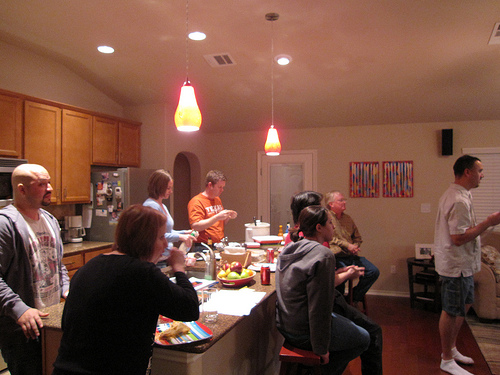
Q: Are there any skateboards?
A: No, there are no skateboards.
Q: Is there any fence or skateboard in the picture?
A: No, there are no skateboards or fences.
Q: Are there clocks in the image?
A: No, there are no clocks.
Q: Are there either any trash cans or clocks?
A: No, there are no clocks or trash cans.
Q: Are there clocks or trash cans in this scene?
A: No, there are no clocks or trash cans.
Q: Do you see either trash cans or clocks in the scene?
A: No, there are no clocks or trash cans.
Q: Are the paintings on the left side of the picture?
A: No, the paintings are on the right of the image.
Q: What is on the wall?
A: The paintings are on the wall.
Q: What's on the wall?
A: The paintings are on the wall.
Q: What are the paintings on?
A: The paintings are on the wall.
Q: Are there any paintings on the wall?
A: Yes, there are paintings on the wall.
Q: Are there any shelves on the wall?
A: No, there are paintings on the wall.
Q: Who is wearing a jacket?
A: The girl is wearing a jacket.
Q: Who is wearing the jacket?
A: The girl is wearing a jacket.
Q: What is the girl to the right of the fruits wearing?
A: The girl is wearing a jacket.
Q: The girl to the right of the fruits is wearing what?
A: The girl is wearing a jacket.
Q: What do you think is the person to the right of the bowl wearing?
A: The girl is wearing a jacket.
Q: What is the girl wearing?
A: The girl is wearing a jacket.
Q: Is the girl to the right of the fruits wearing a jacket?
A: Yes, the girl is wearing a jacket.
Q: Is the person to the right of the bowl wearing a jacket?
A: Yes, the girl is wearing a jacket.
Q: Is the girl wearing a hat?
A: No, the girl is wearing a jacket.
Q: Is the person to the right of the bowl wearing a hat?
A: No, the girl is wearing a jacket.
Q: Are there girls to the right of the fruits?
A: Yes, there is a girl to the right of the fruits.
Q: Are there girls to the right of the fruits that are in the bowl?
A: Yes, there is a girl to the right of the fruits.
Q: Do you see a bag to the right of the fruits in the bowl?
A: No, there is a girl to the right of the fruits.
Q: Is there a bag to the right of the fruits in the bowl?
A: No, there is a girl to the right of the fruits.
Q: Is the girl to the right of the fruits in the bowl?
A: Yes, the girl is to the right of the fruits.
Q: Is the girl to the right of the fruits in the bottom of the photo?
A: Yes, the girl is to the right of the fruits.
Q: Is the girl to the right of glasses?
A: No, the girl is to the right of the fruits.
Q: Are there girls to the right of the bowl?
A: Yes, there is a girl to the right of the bowl.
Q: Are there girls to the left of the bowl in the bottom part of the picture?
A: No, the girl is to the right of the bowl.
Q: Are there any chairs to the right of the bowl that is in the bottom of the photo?
A: No, there is a girl to the right of the bowl.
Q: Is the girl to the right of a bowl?
A: Yes, the girl is to the right of a bowl.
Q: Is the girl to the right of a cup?
A: No, the girl is to the right of a bowl.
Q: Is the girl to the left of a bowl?
A: No, the girl is to the right of a bowl.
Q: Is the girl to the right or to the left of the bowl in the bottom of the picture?
A: The girl is to the right of the bowl.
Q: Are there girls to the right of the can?
A: Yes, there is a girl to the right of the can.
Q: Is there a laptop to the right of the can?
A: No, there is a girl to the right of the can.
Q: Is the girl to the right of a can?
A: Yes, the girl is to the right of a can.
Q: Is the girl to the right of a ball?
A: No, the girl is to the right of a can.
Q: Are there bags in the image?
A: No, there are no bags.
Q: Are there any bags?
A: No, there are no bags.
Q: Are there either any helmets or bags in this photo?
A: No, there are no bags or helmets.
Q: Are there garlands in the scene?
A: No, there are no garlands.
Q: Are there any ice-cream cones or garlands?
A: No, there are no garlands or ice-cream cones.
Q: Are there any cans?
A: Yes, there is a can.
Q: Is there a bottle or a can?
A: Yes, there is a can.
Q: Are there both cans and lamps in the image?
A: Yes, there are both a can and a lamp.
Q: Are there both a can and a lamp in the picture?
A: Yes, there are both a can and a lamp.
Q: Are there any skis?
A: No, there are no skis.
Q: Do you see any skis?
A: No, there are no skis.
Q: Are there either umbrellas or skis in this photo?
A: No, there are no skis or umbrellas.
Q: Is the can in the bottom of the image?
A: Yes, the can is in the bottom of the image.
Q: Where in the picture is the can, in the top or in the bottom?
A: The can is in the bottom of the image.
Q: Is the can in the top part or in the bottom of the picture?
A: The can is in the bottom of the image.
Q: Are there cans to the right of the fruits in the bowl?
A: Yes, there is a can to the right of the fruits.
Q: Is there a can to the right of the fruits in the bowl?
A: Yes, there is a can to the right of the fruits.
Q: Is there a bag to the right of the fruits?
A: No, there is a can to the right of the fruits.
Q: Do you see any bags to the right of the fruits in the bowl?
A: No, there is a can to the right of the fruits.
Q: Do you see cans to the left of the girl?
A: Yes, there is a can to the left of the girl.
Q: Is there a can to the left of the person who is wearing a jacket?
A: Yes, there is a can to the left of the girl.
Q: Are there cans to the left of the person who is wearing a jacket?
A: Yes, there is a can to the left of the girl.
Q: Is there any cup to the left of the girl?
A: No, there is a can to the left of the girl.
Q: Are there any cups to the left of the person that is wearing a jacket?
A: No, there is a can to the left of the girl.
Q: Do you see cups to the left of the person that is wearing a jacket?
A: No, there is a can to the left of the girl.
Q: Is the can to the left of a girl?
A: Yes, the can is to the left of a girl.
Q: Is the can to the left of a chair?
A: No, the can is to the left of a girl.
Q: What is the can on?
A: The can is on the counter.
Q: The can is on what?
A: The can is on the counter.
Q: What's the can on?
A: The can is on the counter.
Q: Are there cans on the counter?
A: Yes, there is a can on the counter.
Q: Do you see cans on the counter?
A: Yes, there is a can on the counter.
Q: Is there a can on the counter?
A: Yes, there is a can on the counter.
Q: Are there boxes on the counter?
A: No, there is a can on the counter.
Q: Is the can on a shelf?
A: No, the can is on the counter.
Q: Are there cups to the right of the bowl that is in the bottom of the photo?
A: No, there is a can to the right of the bowl.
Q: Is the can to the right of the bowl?
A: Yes, the can is to the right of the bowl.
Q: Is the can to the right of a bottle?
A: No, the can is to the right of the bowl.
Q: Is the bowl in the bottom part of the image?
A: Yes, the bowl is in the bottom of the image.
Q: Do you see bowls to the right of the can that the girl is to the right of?
A: No, the bowl is to the left of the can.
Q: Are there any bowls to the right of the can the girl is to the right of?
A: No, the bowl is to the left of the can.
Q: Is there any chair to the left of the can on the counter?
A: No, there is a bowl to the left of the can.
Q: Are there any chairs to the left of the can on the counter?
A: No, there is a bowl to the left of the can.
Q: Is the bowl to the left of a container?
A: No, the bowl is to the left of a can.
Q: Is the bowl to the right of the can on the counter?
A: No, the bowl is to the left of the can.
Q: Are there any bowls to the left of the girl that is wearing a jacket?
A: Yes, there is a bowl to the left of the girl.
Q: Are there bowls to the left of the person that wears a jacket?
A: Yes, there is a bowl to the left of the girl.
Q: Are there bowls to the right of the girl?
A: No, the bowl is to the left of the girl.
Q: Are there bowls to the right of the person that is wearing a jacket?
A: No, the bowl is to the left of the girl.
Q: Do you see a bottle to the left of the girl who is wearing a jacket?
A: No, there is a bowl to the left of the girl.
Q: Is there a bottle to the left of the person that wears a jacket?
A: No, there is a bowl to the left of the girl.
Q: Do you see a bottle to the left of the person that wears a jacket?
A: No, there is a bowl to the left of the girl.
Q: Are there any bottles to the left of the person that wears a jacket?
A: No, there is a bowl to the left of the girl.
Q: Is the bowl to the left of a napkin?
A: No, the bowl is to the left of the girl.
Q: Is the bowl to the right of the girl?
A: No, the bowl is to the left of the girl.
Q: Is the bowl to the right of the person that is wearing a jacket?
A: No, the bowl is to the left of the girl.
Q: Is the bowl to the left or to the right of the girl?
A: The bowl is to the left of the girl.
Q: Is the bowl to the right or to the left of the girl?
A: The bowl is to the left of the girl.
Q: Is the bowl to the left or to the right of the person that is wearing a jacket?
A: The bowl is to the left of the girl.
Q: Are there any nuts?
A: No, there are no nuts.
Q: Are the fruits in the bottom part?
A: Yes, the fruits are in the bottom of the image.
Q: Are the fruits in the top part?
A: No, the fruits are in the bottom of the image.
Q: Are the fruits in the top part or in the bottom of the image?
A: The fruits are in the bottom of the image.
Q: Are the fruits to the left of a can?
A: Yes, the fruits are to the left of a can.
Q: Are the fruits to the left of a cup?
A: No, the fruits are to the left of a can.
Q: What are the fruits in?
A: The fruits are in the bowl.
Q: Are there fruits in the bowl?
A: Yes, there are fruits in the bowl.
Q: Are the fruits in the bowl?
A: Yes, the fruits are in the bowl.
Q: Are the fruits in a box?
A: No, the fruits are in the bowl.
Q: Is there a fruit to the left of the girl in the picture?
A: Yes, there are fruits to the left of the girl.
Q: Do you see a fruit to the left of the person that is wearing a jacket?
A: Yes, there are fruits to the left of the girl.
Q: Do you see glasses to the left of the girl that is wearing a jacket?
A: No, there are fruits to the left of the girl.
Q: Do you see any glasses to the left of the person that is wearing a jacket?
A: No, there are fruits to the left of the girl.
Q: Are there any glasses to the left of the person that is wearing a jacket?
A: No, there are fruits to the left of the girl.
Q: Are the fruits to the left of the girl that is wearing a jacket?
A: Yes, the fruits are to the left of the girl.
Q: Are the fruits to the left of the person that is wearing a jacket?
A: Yes, the fruits are to the left of the girl.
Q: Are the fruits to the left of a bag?
A: No, the fruits are to the left of the girl.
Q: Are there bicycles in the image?
A: No, there are no bicycles.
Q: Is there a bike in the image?
A: No, there are no bikes.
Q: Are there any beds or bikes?
A: No, there are no bikes or beds.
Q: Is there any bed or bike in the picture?
A: No, there are no bikes or beds.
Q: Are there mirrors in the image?
A: No, there are no mirrors.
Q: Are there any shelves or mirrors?
A: No, there are no mirrors or shelves.